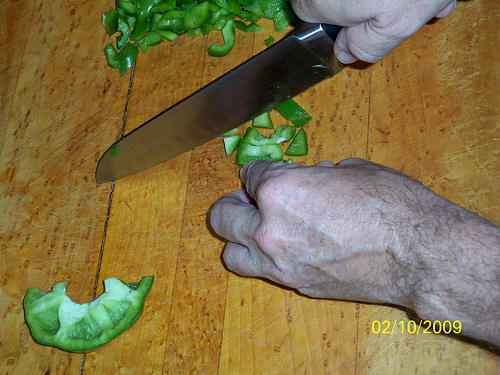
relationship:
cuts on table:
[103, 5, 260, 41] [1, 145, 484, 335]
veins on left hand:
[301, 221, 392, 294] [208, 156, 443, 308]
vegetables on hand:
[219, 130, 310, 163] [209, 156, 433, 310]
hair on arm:
[401, 213, 458, 280] [430, 202, 485, 330]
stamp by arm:
[370, 315, 475, 340] [424, 182, 484, 335]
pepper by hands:
[221, 117, 311, 159] [208, 3, 475, 320]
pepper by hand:
[208, 155, 417, 305] [211, 162, 406, 298]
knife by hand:
[71, 17, 338, 184] [287, 0, 437, 54]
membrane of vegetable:
[55, 275, 125, 317] [22, 273, 159, 354]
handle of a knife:
[331, 21, 348, 29] [147, 116, 197, 142]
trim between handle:
[308, 32, 327, 55] [326, 19, 338, 35]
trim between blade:
[308, 32, 327, 55] [139, 128, 169, 154]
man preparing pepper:
[206, 1, 484, 346] [233, 128, 285, 164]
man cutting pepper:
[209, 1, 499, 346] [233, 128, 285, 164]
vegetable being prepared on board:
[218, 96, 310, 168] [0, 1, 499, 371]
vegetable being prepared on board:
[22, 273, 159, 354] [0, 1, 499, 371]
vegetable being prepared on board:
[99, 1, 297, 78] [0, 1, 499, 371]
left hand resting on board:
[203, 156, 438, 308] [0, 1, 499, 371]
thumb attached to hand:
[331, 16, 421, 66] [289, 0, 457, 67]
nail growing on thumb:
[337, 48, 357, 66] [332, 17, 413, 67]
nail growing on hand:
[337, 48, 357, 66] [287, 0, 460, 65]